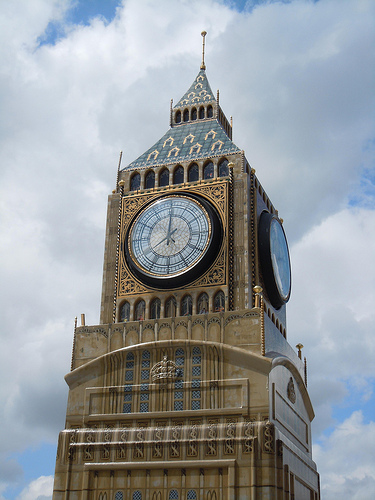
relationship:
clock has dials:
[256, 205, 296, 312] [274, 242, 285, 273]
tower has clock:
[57, 30, 321, 496] [121, 182, 227, 286]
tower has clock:
[57, 30, 321, 496] [255, 210, 315, 311]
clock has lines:
[125, 193, 213, 282] [131, 200, 210, 275]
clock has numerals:
[125, 193, 213, 282] [128, 195, 212, 276]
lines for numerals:
[131, 200, 210, 275] [128, 195, 212, 276]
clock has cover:
[125, 193, 213, 282] [267, 215, 294, 300]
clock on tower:
[125, 193, 213, 282] [57, 30, 321, 496]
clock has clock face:
[125, 188, 209, 276] [134, 201, 204, 274]